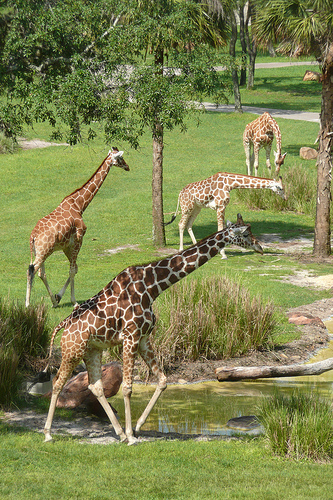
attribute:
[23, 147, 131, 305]
giraffe — rothschild, walking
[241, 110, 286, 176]
giraffe — rothschild, tall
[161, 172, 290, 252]
giraffe — rothschild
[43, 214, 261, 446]
giraffe — rothschild, bent over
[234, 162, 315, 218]
grass — tall, green, patchy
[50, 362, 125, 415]
boulder — large, red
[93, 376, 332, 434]
water — shallow, sun dappled, green, murky, stagnant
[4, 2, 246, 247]
tree — young, tall, leafy, green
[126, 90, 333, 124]
pathway — grey, concrete, paved, dirt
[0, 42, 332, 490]
grounds — green, manicured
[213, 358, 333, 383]
log — long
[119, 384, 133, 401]
knee — knobby, bending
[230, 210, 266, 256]
head — straight out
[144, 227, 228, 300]
neck — long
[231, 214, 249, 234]
horns — pictured